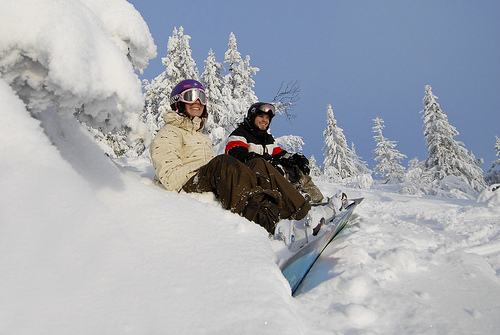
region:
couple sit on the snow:
[116, 47, 376, 292]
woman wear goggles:
[151, 75, 233, 167]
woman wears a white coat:
[146, 67, 232, 193]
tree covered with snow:
[1, 3, 161, 155]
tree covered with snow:
[420, 71, 493, 205]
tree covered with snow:
[371, 114, 414, 194]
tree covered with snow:
[318, 103, 373, 195]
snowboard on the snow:
[283, 190, 364, 295]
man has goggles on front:
[221, 92, 301, 172]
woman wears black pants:
[144, 68, 334, 256]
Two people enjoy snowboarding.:
[148, 77, 367, 295]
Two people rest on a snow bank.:
[145, 78, 372, 300]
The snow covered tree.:
[417, 80, 487, 195]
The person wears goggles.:
[177, 86, 211, 106]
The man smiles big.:
[245, 100, 280, 131]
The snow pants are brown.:
[195, 148, 312, 233]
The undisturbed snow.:
[31, 190, 238, 308]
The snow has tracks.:
[391, 188, 493, 278]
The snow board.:
[279, 218, 346, 295]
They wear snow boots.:
[273, 210, 328, 243]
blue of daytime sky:
[138, 2, 498, 180]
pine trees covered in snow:
[158, 27, 489, 175]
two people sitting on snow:
[149, 80, 351, 294]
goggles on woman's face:
[169, 87, 207, 104]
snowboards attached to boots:
[274, 193, 361, 292]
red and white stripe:
[228, 134, 285, 156]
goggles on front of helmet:
[244, 101, 276, 121]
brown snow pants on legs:
[189, 149, 307, 228]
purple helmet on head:
[168, 78, 204, 111]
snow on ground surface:
[1, 196, 493, 333]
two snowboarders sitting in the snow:
[145, 73, 366, 295]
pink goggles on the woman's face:
[167, 86, 209, 106]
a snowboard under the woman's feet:
[277, 203, 357, 296]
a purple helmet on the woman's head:
[172, 78, 207, 113]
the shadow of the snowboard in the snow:
[295, 232, 355, 295]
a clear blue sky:
[129, 0, 499, 182]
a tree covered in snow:
[415, 82, 490, 189]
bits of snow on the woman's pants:
[234, 174, 281, 215]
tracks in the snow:
[381, 200, 465, 242]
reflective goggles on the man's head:
[256, 101, 278, 116]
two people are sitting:
[97, 13, 429, 323]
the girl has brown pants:
[182, 146, 497, 306]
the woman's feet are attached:
[250, 190, 451, 326]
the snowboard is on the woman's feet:
[265, 210, 396, 325]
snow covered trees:
[305, 113, 452, 333]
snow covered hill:
[22, 153, 329, 332]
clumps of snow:
[25, 36, 157, 192]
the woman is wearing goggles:
[152, 70, 247, 121]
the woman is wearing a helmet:
[165, 88, 245, 155]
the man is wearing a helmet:
[229, 89, 272, 129]